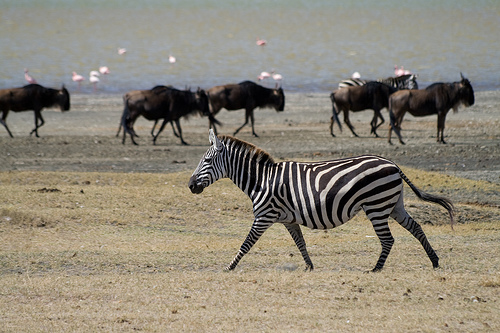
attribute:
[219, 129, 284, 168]
hair — black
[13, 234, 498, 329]
ground — brown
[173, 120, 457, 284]
zebra — black, white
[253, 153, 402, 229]
body — black , white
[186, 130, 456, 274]
animal — running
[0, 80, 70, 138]
animal — running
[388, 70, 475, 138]
animal — running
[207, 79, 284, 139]
animal — running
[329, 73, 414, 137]
animal — running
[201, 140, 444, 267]
coat — striped